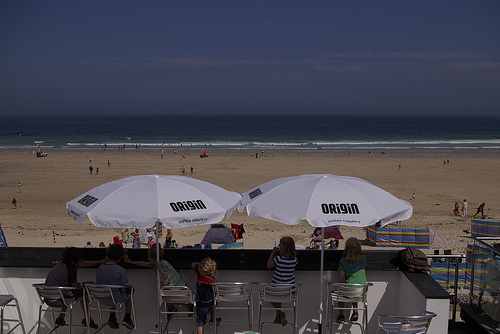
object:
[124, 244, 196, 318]
person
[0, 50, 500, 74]
clouds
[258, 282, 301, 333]
chair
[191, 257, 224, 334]
person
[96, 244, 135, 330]
person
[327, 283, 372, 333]
chair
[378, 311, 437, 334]
chair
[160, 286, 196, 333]
chair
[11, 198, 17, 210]
person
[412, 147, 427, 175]
floater part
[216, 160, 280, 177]
sand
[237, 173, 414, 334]
umbrella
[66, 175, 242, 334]
umbrella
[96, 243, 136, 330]
boy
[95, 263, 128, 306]
shirt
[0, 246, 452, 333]
table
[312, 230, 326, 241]
people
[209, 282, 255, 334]
chair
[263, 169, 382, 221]
umbrella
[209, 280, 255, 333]
back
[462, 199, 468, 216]
person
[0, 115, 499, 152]
sea water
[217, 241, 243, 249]
table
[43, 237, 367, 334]
kids sitting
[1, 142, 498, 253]
beach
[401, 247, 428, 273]
brown bag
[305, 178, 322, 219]
edge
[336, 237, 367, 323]
girl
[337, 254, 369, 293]
shirt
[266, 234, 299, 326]
person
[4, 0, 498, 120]
sky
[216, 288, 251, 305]
seat